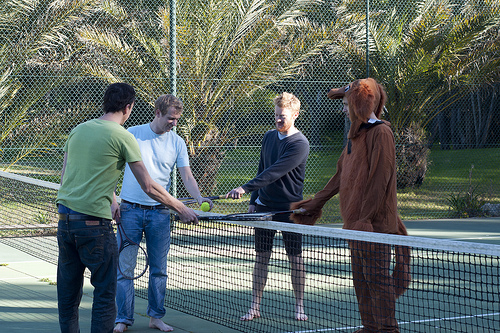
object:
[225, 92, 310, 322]
man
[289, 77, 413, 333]
man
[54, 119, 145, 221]
shirt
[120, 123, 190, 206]
shirt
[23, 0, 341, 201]
bush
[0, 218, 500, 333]
court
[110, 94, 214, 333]
man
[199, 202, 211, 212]
ball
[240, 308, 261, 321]
foot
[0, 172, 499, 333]
net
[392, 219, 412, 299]
tail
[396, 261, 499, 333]
shadow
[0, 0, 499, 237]
fence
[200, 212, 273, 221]
racket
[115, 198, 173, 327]
pants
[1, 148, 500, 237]
grass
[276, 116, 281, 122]
nose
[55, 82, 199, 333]
man